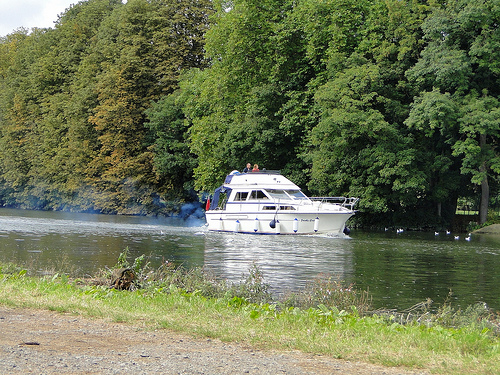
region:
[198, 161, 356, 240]
one large white boat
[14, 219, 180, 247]
section of greenish rippled body of water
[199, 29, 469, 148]
sunlit green tree leaves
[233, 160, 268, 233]
two people atop white boat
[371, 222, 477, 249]
white birds bobbing along river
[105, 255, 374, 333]
grass growing along side of river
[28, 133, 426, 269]
white boat on green river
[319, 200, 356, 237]
front of white boat in water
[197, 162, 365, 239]
A boat in the water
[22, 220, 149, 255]
A large body of water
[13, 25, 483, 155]
Trees near the boat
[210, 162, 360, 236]
A big white boat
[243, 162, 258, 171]
Two people standing on top the boat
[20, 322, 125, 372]
A gravel path near green grass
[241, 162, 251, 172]
A man standing on a boat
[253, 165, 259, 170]
A lady standing on a boat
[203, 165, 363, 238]
A boat in the water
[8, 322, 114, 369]
A light brown gravel road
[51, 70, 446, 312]
a boat on the water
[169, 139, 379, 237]
the boat is white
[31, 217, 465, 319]
the water is murky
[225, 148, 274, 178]
people on the boat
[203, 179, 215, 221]
a red object on the stern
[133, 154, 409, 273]
the boat is on the river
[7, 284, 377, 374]
a sandy area next the water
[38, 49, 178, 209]
some of the leaves are brown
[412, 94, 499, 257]
a tree in the area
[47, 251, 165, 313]
a clump of vegetation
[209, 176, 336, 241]
white and blue boat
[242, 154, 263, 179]
people standing on boat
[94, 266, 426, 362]
green grass near water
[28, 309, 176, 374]
grey and rocky path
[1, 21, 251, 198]
green and brown trees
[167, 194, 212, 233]
blue smoke behind boat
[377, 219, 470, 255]
white ducks on water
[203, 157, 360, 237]
A white boat on the water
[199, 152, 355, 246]
A white boat on the lake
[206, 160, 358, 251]
A white boat moving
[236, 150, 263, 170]
Two people on the boat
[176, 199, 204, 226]
Smoke from the boat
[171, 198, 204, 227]
Exhaust from the boat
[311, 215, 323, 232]
A safety device on the boat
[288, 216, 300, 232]
A safety device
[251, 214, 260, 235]
A safety device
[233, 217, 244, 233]
A safety device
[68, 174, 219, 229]
the smoke is gray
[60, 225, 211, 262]
the water is green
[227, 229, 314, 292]
reflection on the water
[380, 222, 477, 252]
ducks in the water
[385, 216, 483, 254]
the ducks are white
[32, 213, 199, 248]
the water is ruffled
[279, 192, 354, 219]
rails on the boat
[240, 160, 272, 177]
people on the boat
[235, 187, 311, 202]
windows on the boat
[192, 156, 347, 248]
A boat in the water.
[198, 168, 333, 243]
The boat is white.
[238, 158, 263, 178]
People standing on top of boat.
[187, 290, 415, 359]
The grass is green.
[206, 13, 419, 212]
Trees behind the boat.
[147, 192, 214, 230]
Smoke coming from back of boat.